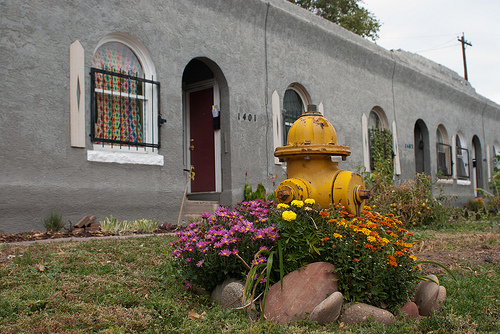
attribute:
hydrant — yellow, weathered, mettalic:
[271, 102, 374, 221]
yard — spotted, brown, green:
[1, 206, 499, 332]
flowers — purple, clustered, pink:
[168, 197, 284, 325]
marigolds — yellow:
[272, 196, 324, 275]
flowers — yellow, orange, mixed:
[275, 194, 459, 333]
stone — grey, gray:
[0, 1, 499, 243]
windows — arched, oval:
[85, 29, 499, 189]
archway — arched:
[179, 53, 237, 228]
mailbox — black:
[209, 110, 225, 133]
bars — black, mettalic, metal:
[86, 64, 170, 154]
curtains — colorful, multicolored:
[91, 40, 146, 148]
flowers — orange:
[315, 200, 426, 317]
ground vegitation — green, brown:
[0, 205, 499, 332]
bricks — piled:
[72, 213, 100, 233]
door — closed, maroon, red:
[187, 85, 219, 194]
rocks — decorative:
[208, 258, 449, 334]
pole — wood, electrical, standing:
[455, 32, 474, 85]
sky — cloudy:
[292, 0, 500, 105]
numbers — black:
[236, 110, 259, 124]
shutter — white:
[63, 38, 493, 185]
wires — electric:
[418, 31, 499, 58]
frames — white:
[67, 32, 498, 186]